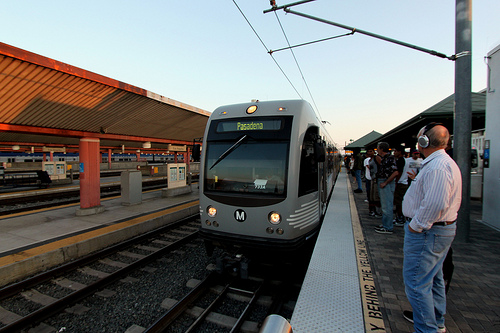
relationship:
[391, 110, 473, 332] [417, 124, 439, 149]
man wearing headphones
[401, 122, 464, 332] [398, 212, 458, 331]
man wearing jeans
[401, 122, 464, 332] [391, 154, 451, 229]
man wearing shirt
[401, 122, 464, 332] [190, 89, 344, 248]
man waiting for a train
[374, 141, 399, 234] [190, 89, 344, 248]
man waiting for a train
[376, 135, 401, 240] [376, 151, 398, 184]
man wearing a black shirt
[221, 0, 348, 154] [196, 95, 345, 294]
wires over train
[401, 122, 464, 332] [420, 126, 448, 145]
man with hair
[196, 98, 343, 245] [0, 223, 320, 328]
train on railroad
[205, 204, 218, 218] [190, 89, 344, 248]
headlight on a train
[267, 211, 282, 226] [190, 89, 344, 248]
headlight on a train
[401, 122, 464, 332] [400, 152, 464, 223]
man wearing a shirt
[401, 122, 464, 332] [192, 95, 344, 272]
man waiting for a train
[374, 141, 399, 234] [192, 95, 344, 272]
man waiting for a train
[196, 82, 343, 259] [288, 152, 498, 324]
train stopping at a platform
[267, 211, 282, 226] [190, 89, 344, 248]
headlight on train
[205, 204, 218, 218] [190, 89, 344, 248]
headlight on train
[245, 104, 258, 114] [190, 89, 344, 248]
light on train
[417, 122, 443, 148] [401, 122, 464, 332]
headphones on man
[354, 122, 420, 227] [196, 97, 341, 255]
people standing near train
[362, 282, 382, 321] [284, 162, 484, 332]
word on ground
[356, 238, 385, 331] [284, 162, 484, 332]
word on ground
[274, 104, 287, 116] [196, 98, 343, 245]
light on train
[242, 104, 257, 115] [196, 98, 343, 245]
light on train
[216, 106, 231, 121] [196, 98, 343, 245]
light on train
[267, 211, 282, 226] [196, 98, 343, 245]
headlight on train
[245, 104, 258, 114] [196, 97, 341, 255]
light on train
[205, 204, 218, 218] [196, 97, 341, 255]
headlight on train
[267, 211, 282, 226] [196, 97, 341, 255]
headlight on train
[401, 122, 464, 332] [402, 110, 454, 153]
man wears headphones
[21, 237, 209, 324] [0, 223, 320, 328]
gravel cover railroad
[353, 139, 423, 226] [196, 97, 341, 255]
people on train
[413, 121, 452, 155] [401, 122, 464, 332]
head of man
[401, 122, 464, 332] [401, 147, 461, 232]
man wearing shirt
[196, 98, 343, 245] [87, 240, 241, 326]
train on track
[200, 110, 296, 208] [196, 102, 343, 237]
windshield on train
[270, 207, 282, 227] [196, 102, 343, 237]
headlight on train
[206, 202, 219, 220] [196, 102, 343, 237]
headlight on train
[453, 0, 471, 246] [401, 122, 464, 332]
pole behind man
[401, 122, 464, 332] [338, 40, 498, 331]
man at station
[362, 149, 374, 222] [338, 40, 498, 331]
person at station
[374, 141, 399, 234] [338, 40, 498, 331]
man at station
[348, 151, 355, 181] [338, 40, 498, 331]
person at station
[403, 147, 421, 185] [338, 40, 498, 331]
person at station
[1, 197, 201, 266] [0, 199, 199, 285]
lines on border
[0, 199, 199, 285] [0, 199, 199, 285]
border of border